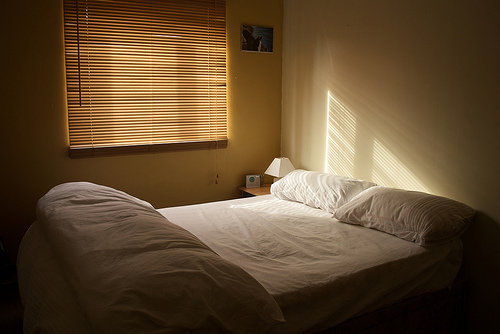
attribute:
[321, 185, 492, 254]
pillow — white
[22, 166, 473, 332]
bed — queen size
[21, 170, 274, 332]
pillow — large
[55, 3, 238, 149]
blinds — wooden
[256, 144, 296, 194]
lamp — small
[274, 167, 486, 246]
pillows —  large, white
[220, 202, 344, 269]
sheets — white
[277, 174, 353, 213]
pillowcases — white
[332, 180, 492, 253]
pillow — white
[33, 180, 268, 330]
comforter — white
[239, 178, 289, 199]
nightstand — wooden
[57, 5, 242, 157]
window — big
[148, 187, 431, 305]
sheet — white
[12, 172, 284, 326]
comforter — white, queen size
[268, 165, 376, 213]
pillow — white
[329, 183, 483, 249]
pillow — white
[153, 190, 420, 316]
sheets — white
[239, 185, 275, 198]
night stand — small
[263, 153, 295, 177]
lampshade — white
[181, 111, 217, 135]
shades — closed